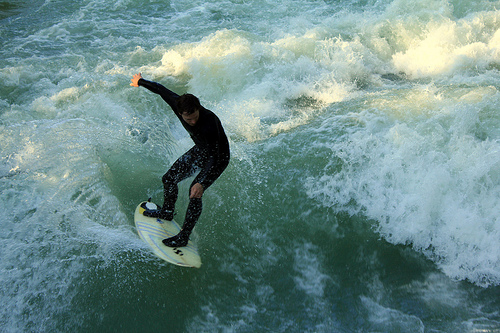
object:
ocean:
[2, 2, 499, 332]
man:
[126, 72, 232, 250]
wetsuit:
[138, 79, 232, 248]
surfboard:
[132, 197, 204, 270]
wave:
[52, 5, 498, 135]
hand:
[126, 71, 144, 90]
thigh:
[162, 146, 194, 179]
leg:
[161, 147, 194, 214]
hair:
[177, 92, 200, 117]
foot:
[162, 229, 191, 249]